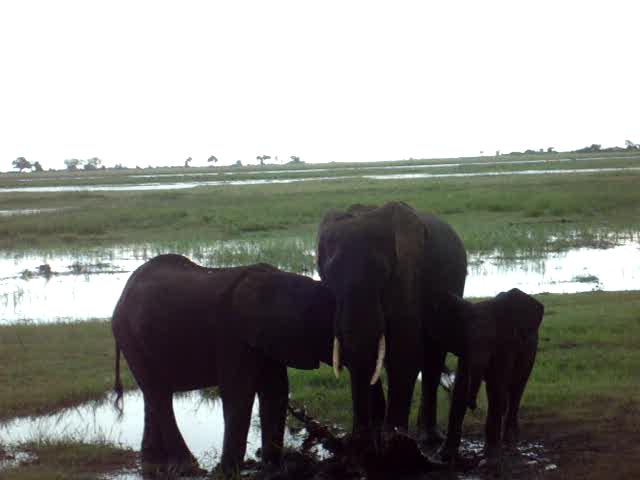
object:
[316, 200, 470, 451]
elephant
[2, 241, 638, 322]
water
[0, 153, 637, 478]
grass